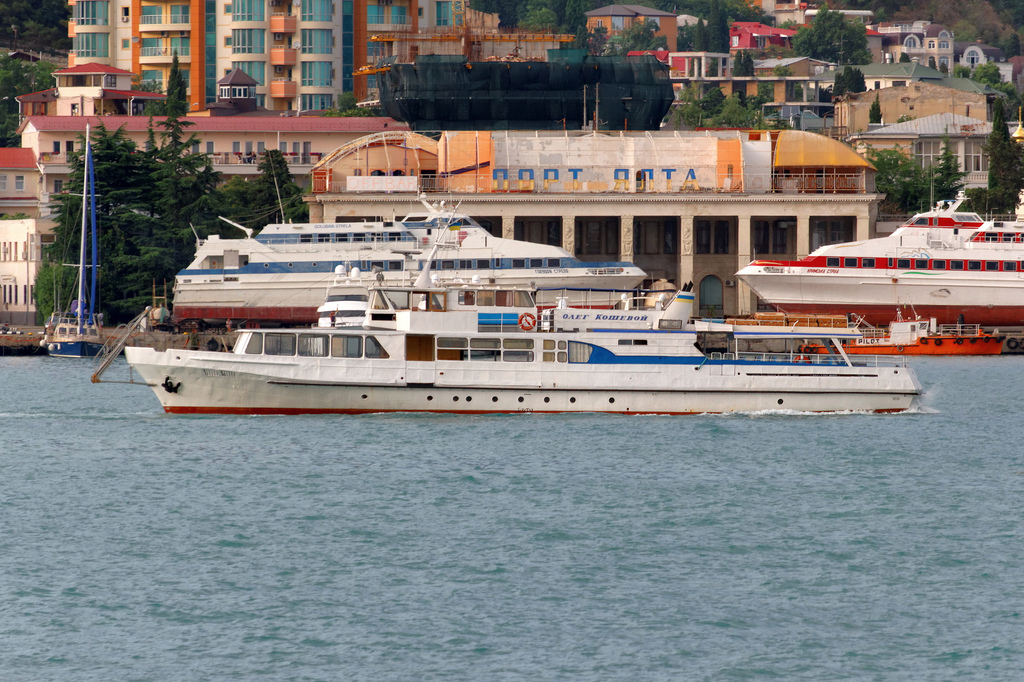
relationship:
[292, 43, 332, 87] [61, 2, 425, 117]
window on a building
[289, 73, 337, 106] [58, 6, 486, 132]
window on a building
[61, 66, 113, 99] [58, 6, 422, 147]
window on a building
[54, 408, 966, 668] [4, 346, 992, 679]
ripples in water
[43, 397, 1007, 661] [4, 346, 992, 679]
ripples in water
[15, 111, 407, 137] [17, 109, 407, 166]
roof covering building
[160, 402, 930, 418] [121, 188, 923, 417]
bottom belonging to boat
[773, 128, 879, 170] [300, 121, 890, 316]
roof covering building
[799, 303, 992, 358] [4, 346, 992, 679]
boat floating in water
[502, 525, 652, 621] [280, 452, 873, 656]
ripples in water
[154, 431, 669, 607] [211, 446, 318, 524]
ripples in water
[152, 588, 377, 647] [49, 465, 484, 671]
ripples in water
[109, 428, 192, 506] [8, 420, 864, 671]
ripples in water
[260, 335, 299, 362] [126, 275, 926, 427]
window on boat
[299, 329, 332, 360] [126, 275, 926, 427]
window on boat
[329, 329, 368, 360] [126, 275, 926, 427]
window on boat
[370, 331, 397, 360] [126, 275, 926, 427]
window on boat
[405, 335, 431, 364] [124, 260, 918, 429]
window on boat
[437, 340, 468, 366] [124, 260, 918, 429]
window on boat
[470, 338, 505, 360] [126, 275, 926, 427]
window on boat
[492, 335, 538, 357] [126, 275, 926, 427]
window on boat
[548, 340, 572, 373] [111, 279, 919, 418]
window on boat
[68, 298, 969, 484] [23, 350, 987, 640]
boat in water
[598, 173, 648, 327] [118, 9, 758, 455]
windows on building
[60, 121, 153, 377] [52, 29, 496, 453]
tree in front of building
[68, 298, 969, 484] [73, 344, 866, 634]
boat in water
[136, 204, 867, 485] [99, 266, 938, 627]
boat in water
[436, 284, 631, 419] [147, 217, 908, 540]
letters on boat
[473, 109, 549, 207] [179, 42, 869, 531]
letters on building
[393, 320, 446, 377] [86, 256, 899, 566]
window on boat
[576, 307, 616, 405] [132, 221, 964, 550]
window on boat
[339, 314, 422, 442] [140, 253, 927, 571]
window on boat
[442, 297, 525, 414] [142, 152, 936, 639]
window on boat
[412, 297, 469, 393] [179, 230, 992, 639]
window on boat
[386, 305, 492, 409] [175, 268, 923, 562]
window on boat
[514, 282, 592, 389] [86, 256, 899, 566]
window on boat